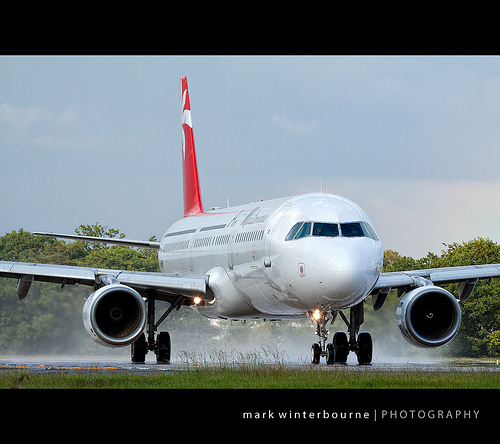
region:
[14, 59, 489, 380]
plane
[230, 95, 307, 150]
white clouds in blue sky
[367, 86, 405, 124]
white clouds in blue sky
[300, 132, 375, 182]
white clouds in blue sky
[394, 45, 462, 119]
white clouds in blue sky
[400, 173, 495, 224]
white clouds in blue sky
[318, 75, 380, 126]
white clouds in blue sky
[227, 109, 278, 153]
white clouds in blue sky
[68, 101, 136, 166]
white clouds in blue sky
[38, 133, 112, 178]
white clouds in blue sky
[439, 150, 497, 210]
white clouds in blue sky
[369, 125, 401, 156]
white clouds in blue sky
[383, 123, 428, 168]
white clouds in blue sky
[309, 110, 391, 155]
white clouds in blue sky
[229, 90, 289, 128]
white clouds in blue sky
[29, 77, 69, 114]
white clouds in blue sky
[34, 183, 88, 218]
white clouds in blue sky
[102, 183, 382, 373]
the plane is white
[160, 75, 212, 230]
plane's tail is red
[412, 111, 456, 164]
white clouds in blue sky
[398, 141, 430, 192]
white clouds in blue sky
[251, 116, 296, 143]
white clouds in blue sky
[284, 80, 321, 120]
white clouds in blue sky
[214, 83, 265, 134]
white clouds in blue sky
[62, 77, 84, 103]
white clouds in blue sky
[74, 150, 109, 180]
white clouds in blue sky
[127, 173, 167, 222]
white clouds in blue sky